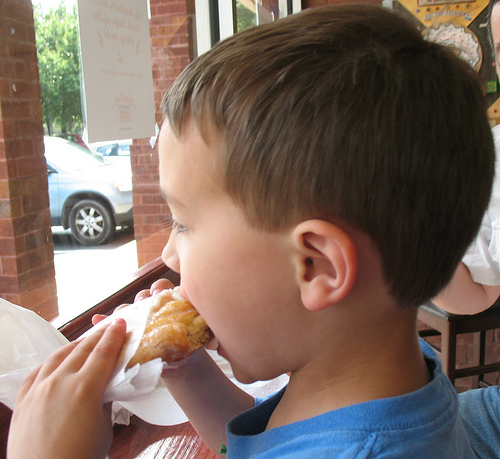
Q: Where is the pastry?
A: In the kid's hands.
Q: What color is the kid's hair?
A: Brown.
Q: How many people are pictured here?
A: 2.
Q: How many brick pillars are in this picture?
A: 2.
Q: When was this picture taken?
A: Daytime.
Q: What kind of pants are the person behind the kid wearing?
A: Jeans.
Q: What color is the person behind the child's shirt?
A: White.